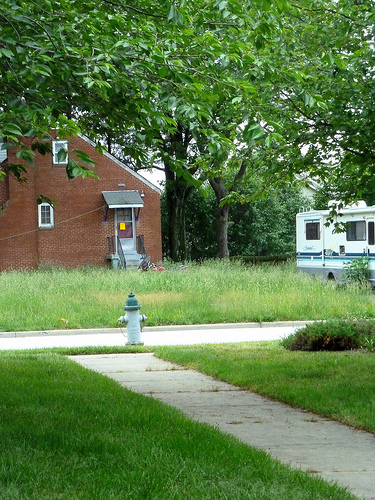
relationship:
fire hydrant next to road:
[118, 290, 152, 345] [0, 319, 328, 358]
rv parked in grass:
[291, 191, 373, 293] [4, 263, 372, 327]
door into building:
[101, 184, 145, 268] [0, 110, 164, 269]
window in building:
[35, 201, 56, 228] [0, 110, 164, 269]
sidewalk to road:
[69, 347, 373, 499] [0, 319, 328, 358]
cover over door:
[103, 190, 143, 211] [101, 184, 145, 268]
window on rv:
[306, 222, 319, 240] [291, 191, 373, 293]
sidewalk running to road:
[69, 347, 373, 499] [0, 319, 328, 358]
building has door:
[0, 110, 164, 269] [101, 184, 145, 268]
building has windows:
[0, 110, 164, 269] [31, 136, 70, 236]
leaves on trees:
[3, 1, 372, 169] [1, 5, 372, 274]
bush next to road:
[289, 315, 362, 352] [0, 319, 328, 358]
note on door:
[119, 220, 128, 232] [101, 184, 145, 268]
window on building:
[35, 201, 56, 228] [0, 110, 164, 269]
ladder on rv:
[295, 203, 311, 216] [291, 191, 373, 293]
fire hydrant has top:
[118, 290, 152, 345] [124, 292, 141, 310]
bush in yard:
[289, 315, 362, 352] [5, 319, 374, 499]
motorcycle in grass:
[135, 259, 166, 273] [4, 263, 372, 327]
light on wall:
[137, 186, 150, 203] [73, 151, 165, 271]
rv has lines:
[291, 191, 373, 293] [298, 250, 374, 270]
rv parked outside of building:
[291, 191, 373, 293] [0, 110, 164, 269]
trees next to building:
[1, 5, 372, 274] [0, 110, 164, 269]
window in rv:
[303, 220, 322, 241] [291, 191, 373, 293]